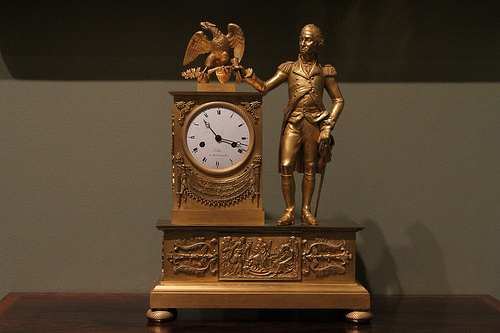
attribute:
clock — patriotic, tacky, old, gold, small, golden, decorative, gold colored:
[146, 20, 374, 326]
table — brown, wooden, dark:
[1, 291, 499, 332]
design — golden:
[165, 236, 218, 277]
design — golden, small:
[217, 231, 301, 281]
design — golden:
[301, 238, 354, 280]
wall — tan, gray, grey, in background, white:
[0, 82, 499, 294]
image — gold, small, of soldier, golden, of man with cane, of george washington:
[240, 22, 345, 226]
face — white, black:
[186, 108, 251, 170]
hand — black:
[203, 119, 223, 142]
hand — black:
[214, 135, 249, 147]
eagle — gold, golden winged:
[181, 21, 244, 80]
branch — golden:
[181, 65, 245, 80]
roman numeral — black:
[215, 109, 223, 117]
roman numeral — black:
[238, 123, 244, 129]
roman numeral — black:
[235, 148, 245, 156]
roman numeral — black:
[201, 155, 208, 165]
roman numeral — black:
[188, 134, 196, 142]